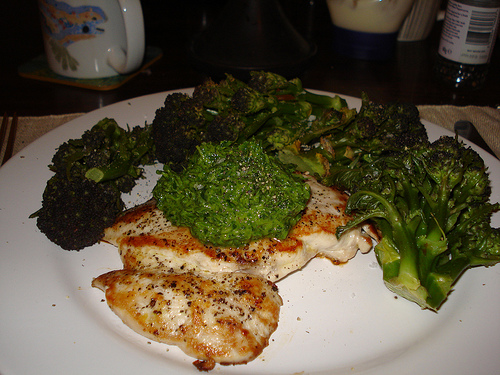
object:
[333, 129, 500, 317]
broccoli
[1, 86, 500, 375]
plate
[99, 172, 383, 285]
meat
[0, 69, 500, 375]
serving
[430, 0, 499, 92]
pepper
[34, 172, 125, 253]
broccoli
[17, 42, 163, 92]
coaster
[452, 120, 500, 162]
knife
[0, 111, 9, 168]
silverware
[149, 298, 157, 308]
seasoning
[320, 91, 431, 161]
vegetable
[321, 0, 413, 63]
bottle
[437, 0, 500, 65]
label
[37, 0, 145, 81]
cups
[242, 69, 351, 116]
piece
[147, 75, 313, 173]
broccoli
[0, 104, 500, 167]
placemat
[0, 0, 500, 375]
table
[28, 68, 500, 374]
food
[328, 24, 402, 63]
lid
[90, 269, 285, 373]
meat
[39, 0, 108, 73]
design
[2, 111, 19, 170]
chopsticks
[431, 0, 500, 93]
grinder